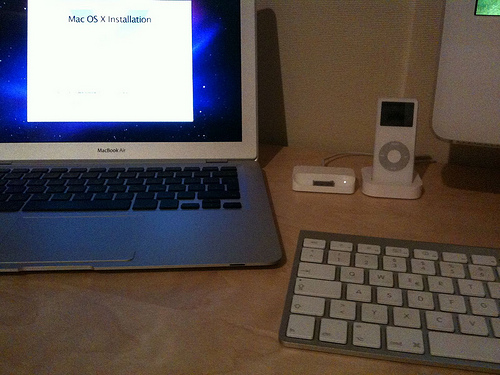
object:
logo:
[95, 147, 127, 154]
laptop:
[0, 0, 284, 268]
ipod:
[372, 81, 419, 186]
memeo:
[49, 27, 217, 135]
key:
[321, 266, 429, 328]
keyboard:
[305, 235, 484, 351]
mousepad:
[0, 212, 137, 263]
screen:
[0, 2, 240, 142]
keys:
[37, 174, 234, 209]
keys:
[363, 241, 449, 304]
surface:
[102, 185, 246, 251]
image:
[26, 0, 195, 122]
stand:
[359, 167, 421, 199]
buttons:
[167, 177, 221, 195]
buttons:
[337, 260, 433, 312]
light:
[341, 178, 349, 186]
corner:
[430, 113, 468, 149]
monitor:
[430, 0, 500, 148]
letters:
[324, 257, 432, 330]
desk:
[140, 285, 238, 347]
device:
[290, 97, 424, 200]